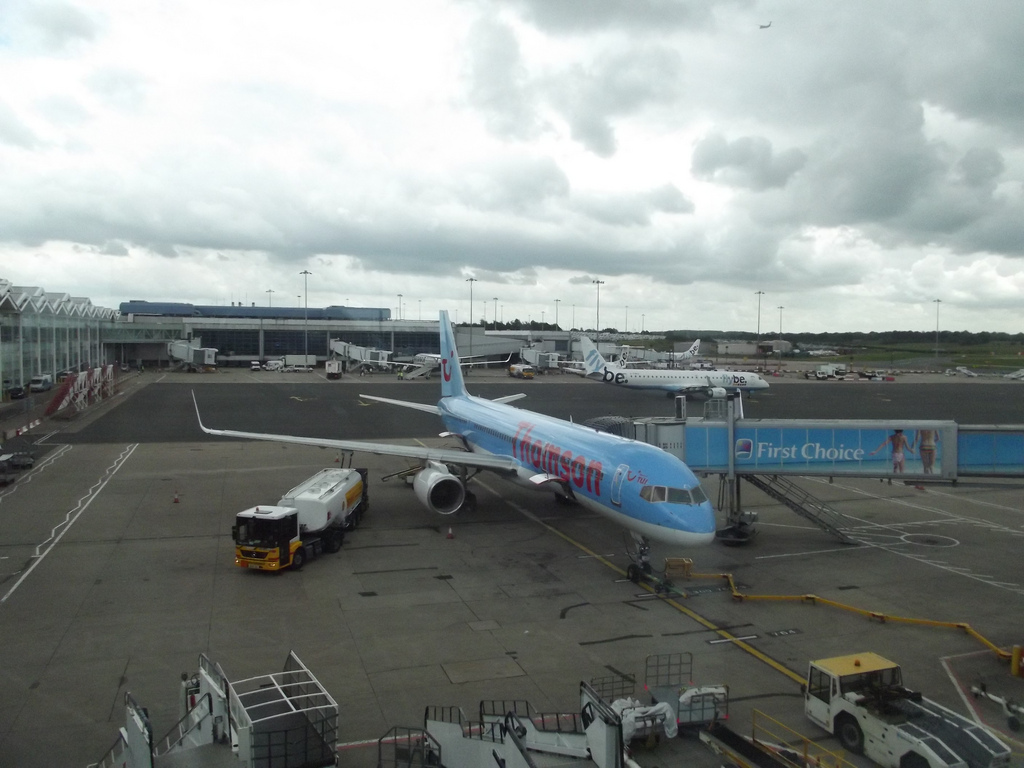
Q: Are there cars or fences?
A: No, there are no cars or fences.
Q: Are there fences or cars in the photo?
A: No, there are no cars or fences.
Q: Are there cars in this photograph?
A: No, there are no cars.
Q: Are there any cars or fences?
A: No, there are no cars or fences.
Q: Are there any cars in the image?
A: No, there are no cars.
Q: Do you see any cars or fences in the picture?
A: No, there are no cars or fences.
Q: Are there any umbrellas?
A: No, there are no umbrellas.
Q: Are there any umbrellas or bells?
A: No, there are no umbrellas or bells.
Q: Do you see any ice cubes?
A: No, there are no ice cubes.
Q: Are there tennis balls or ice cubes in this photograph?
A: No, there are no ice cubes or tennis balls.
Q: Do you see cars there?
A: No, there are no cars.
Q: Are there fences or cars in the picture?
A: No, there are no cars or fences.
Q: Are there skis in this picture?
A: No, there are no skis.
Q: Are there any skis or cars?
A: No, there are no skis or cars.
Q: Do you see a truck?
A: Yes, there is a truck.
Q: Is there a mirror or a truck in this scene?
A: Yes, there is a truck.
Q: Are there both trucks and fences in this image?
A: No, there is a truck but no fences.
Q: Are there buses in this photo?
A: No, there are no buses.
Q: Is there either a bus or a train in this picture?
A: No, there are no buses or trains.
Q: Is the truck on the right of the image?
A: No, the truck is on the left of the image.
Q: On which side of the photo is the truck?
A: The truck is on the left of the image.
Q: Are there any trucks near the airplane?
A: Yes, there is a truck near the airplane.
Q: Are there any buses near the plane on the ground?
A: No, there is a truck near the plane.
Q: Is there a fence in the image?
A: No, there are no fences.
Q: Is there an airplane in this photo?
A: Yes, there is an airplane.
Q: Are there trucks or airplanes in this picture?
A: Yes, there is an airplane.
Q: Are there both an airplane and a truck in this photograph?
A: Yes, there are both an airplane and a truck.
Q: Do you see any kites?
A: No, there are no kites.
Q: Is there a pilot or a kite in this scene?
A: No, there are no kites or pilots.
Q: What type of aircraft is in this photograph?
A: The aircraft is an airplane.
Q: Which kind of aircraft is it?
A: The aircraft is an airplane.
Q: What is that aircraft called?
A: This is an airplane.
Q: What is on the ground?
A: The airplane is on the ground.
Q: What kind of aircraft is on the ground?
A: The aircraft is an airplane.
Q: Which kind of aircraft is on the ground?
A: The aircraft is an airplane.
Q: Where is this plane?
A: The plane is on the ground.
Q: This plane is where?
A: The plane is on the ground.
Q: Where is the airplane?
A: The plane is on the ground.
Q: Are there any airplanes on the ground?
A: Yes, there is an airplane on the ground.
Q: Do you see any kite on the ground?
A: No, there is an airplane on the ground.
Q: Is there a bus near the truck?
A: No, there is an airplane near the truck.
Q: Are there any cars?
A: No, there are no cars.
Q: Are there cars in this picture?
A: No, there are no cars.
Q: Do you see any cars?
A: No, there are no cars.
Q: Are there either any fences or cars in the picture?
A: No, there are no cars or fences.